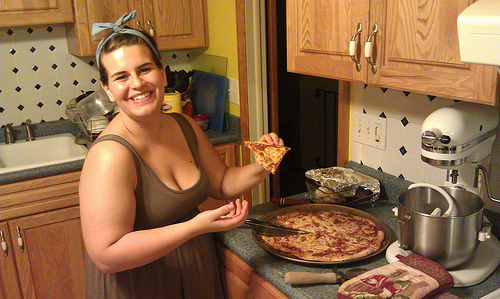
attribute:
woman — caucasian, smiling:
[76, 28, 283, 297]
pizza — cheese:
[259, 208, 382, 265]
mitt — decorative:
[338, 251, 455, 298]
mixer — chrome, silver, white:
[386, 107, 497, 288]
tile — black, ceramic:
[37, 66, 60, 88]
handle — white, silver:
[362, 24, 380, 75]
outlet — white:
[351, 111, 385, 145]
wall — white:
[349, 82, 498, 211]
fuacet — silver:
[21, 119, 43, 141]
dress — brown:
[79, 111, 229, 298]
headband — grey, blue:
[90, 11, 161, 66]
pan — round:
[249, 203, 391, 266]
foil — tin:
[305, 164, 382, 207]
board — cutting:
[188, 68, 229, 132]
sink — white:
[0, 129, 88, 176]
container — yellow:
[157, 90, 183, 115]